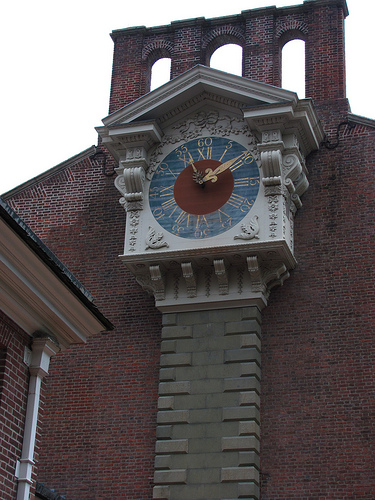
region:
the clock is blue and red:
[43, 106, 307, 381]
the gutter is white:
[11, 331, 73, 491]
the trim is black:
[22, 232, 132, 342]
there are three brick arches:
[121, 22, 317, 139]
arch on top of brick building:
[271, 23, 316, 105]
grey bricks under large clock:
[148, 302, 268, 499]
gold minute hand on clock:
[200, 148, 249, 188]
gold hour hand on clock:
[184, 153, 201, 184]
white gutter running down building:
[11, 339, 61, 499]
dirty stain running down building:
[320, 140, 343, 242]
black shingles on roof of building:
[40, 243, 68, 282]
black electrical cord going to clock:
[87, 151, 120, 179]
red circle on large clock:
[170, 154, 235, 223]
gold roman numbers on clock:
[192, 213, 210, 238]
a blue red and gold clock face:
[147, 135, 260, 240]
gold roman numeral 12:
[195, 144, 211, 160]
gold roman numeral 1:
[216, 147, 226, 162]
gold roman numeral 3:
[229, 176, 249, 188]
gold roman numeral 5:
[215, 207, 227, 224]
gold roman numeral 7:
[173, 208, 191, 226]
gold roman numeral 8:
[156, 195, 176, 217]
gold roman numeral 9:
[158, 182, 173, 198]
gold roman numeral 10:
[163, 166, 178, 178]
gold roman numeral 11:
[178, 150, 192, 167]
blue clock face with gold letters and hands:
[145, 133, 260, 241]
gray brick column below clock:
[151, 305, 265, 498]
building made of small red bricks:
[0, 91, 371, 499]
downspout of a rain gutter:
[4, 328, 58, 498]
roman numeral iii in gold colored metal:
[222, 189, 246, 211]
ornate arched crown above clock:
[93, 0, 354, 113]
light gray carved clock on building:
[95, 61, 330, 316]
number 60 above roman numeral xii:
[193, 134, 215, 149]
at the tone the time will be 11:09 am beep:
[145, 133, 262, 241]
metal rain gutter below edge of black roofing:
[1, 191, 116, 364]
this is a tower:
[0, 0, 372, 497]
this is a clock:
[147, 131, 263, 239]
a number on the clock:
[227, 188, 269, 217]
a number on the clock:
[184, 208, 217, 248]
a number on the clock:
[193, 132, 223, 167]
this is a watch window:
[139, 36, 184, 94]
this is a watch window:
[205, 31, 252, 82]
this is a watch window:
[277, 25, 310, 109]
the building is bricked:
[289, 313, 350, 400]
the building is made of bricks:
[55, 383, 151, 449]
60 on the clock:
[166, 134, 258, 226]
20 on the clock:
[157, 131, 259, 259]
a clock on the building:
[147, 128, 289, 270]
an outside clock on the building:
[133, 104, 284, 296]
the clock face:
[144, 134, 259, 236]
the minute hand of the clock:
[203, 140, 256, 185]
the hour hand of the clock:
[180, 137, 203, 193]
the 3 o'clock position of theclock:
[234, 174, 261, 190]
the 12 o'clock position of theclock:
[197, 129, 212, 170]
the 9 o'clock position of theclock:
[150, 181, 176, 198]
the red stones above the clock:
[108, 17, 336, 103]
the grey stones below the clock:
[159, 303, 264, 495]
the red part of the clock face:
[174, 158, 232, 211]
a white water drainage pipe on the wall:
[17, 334, 49, 495]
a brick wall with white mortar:
[0, 318, 50, 491]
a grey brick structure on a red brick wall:
[135, 304, 291, 497]